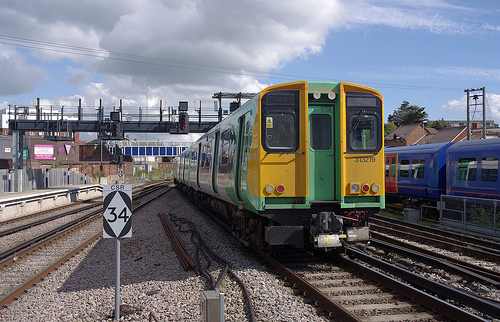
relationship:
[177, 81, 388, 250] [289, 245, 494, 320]
train on tracks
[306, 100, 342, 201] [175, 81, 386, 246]
door for train car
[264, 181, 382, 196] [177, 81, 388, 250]
lights on train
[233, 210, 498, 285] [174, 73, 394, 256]
tracks near train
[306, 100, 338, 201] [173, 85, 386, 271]
door on train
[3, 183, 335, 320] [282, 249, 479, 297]
pebbles near train tracks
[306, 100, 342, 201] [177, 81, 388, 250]
door on train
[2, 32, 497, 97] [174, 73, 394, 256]
power lines over train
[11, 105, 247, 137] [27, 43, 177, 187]
bridge on background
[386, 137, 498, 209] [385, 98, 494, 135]
train in background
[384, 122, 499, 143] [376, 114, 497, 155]
roofs on nearby homes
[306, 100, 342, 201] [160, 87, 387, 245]
door at end train